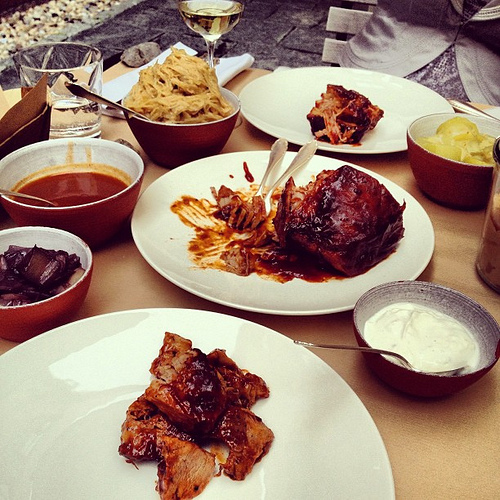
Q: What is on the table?
A: Bowls and plates of food.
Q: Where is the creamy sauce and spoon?
A: In a ceramic bowl.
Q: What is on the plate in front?
A: Cut meat with glazed sauce.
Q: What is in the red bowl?
A: Hot sauce and a utensil.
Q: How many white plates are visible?
A: Three.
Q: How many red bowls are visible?
A: Five.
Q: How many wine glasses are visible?
A: One.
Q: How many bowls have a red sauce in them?
A: One.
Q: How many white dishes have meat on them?
A: Three.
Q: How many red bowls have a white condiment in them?
A: One.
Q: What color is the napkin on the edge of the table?
A: White.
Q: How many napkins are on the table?
A: One.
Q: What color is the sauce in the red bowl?
A: Red.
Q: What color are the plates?
A: White.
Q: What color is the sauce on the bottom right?
A: White.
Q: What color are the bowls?
A: Red.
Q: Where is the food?
A: On a table.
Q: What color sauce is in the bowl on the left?
A: Red.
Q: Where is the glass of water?
A: On the table.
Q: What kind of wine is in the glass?
A: White.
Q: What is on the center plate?
A: Meat covered in sauce.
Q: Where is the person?
A: Sitting at the table.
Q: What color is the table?
A: Tan.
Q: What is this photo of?
A: Sweet potatoes in a bowl.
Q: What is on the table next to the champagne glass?
A: A white napkin.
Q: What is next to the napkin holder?
A: A glass cup.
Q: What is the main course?
A: Meat with sauce.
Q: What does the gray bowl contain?
A: Cream.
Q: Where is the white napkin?
A: Next to the glass of wine.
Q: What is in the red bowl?
A: Red sauce.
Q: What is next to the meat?
A: White sauce in a bowl.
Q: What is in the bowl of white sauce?
A: A spoon.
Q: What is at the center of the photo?
A: A meat dish on a white plate.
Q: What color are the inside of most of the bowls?
A: White.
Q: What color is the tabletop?
A: Brown.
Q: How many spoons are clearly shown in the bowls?
A: 3.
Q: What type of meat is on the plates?
A: Pork.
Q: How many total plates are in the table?
A: 3.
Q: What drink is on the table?
A: White wine.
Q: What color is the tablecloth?
A: Brown.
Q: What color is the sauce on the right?
A: White.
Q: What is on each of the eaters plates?
A: Pork loin.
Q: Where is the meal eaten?
A: On a patio.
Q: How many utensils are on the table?
A: Five.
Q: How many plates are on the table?
A: Three.